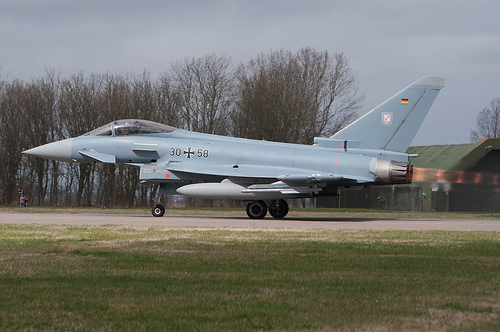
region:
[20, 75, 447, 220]
Fighter jet parked on runway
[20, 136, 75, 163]
Gray nosecone on front of fighter jet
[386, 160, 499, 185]
Engines running on back of jet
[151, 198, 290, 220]
Landing gear tires on the runway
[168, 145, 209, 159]
Numbers on side of jet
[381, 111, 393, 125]
Logo on tail of fighter jet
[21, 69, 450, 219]
German fighter jet taking off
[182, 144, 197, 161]
symbol on the grey jet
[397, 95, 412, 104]
symbol on the grey jet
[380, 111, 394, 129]
symbol on the grey jet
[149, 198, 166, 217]
wheel on the grey jet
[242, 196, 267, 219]
wheel on the grey jet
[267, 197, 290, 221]
wheel on the grey jet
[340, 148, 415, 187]
engine on the grey jet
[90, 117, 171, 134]
cockpit on the grey jet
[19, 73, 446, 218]
A fighter jet on the ground.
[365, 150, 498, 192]
The jet engine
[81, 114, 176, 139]
The cockpit of the plane.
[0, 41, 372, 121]
Trees in the background.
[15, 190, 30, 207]
People standing in the distance.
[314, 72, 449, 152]
Tail of the fighter jet.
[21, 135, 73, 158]
The nose of the plane.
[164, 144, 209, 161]
A number on the side of the plane.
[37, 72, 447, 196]
gray jet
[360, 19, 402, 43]
white clouds in blue sky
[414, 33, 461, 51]
white clouds in blue sky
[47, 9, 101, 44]
white clouds in blue sky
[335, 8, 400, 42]
white clouds in blue sky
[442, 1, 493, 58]
white clouds in blue sky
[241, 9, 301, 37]
white clouds in blue sky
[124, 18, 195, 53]
white clouds in blue sky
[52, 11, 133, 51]
white clouds in blue sky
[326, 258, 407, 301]
the grass is low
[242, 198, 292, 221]
tires on the plane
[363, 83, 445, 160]
tail of the plane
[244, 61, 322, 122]
the branches on the tree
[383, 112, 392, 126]
a sign on the tail of the plane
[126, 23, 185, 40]
the sky is grey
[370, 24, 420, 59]
a grey sky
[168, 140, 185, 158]
number on the plane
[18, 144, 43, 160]
nose of the plane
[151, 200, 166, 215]
the wheel on the plane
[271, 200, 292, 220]
a wheel on plane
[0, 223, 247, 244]
bare spot on the grass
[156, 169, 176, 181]
a red circle on plane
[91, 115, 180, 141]
the window of plane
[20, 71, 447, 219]
gray-blue fighter jet on runway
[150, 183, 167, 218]
front landing gear of fighter jet